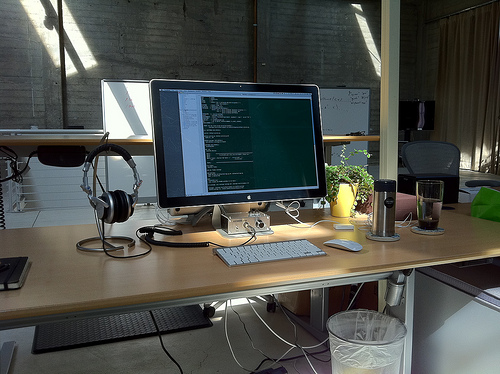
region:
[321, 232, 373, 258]
white wireless computer mouse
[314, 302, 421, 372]
waste basket under the desk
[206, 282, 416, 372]
cords hanging under the desk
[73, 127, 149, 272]
headset on a stand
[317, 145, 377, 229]
plant in a yellow pot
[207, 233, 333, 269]
silver and white computer keyboard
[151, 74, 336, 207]
computer monitor is on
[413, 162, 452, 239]
glass of water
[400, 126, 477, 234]
black desk chair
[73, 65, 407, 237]
whiteboard behind the computer desk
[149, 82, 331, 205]
an apple computer moniter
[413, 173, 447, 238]
a glass of water half full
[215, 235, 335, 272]
a keyboard with white keys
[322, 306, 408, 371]
an empty trash can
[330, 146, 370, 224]
a plant in a yellow pot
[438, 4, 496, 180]
part of a long curtain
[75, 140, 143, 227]
a pair of silver and black headphones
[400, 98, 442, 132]
part of a flat screen tv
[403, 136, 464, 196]
the back of a chair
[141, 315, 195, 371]
a black cable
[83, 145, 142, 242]
headphones hanging on desk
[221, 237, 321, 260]
keyboard on the desk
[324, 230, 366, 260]
mouse on the desk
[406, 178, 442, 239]
glass of the water on desk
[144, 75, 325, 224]
large computer on desk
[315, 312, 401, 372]
garbage can under computer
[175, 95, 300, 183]
screen on desk top computer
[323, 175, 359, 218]
yellow flower pot on desk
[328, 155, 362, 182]
green plant in pot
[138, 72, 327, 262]
computer on desk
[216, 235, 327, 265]
White wireless computer keyboard.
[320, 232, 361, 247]
White wireless computer mouse.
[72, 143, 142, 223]
Silver and black headphones.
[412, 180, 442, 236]
Glass of water sitting on a coaster.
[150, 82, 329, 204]
Flat screen computer moniter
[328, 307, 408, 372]
Waste paper basket with plastic lining.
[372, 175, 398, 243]
Therma coffee container sitting on a coaster.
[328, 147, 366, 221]
Small plant in yellow vase.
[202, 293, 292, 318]
Rollers on an office chair.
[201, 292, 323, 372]
Connection wires to computer.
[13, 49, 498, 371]
an office space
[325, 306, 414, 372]
a wastebasket with a plastic bag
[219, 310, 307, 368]
a bunch of wires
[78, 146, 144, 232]
silvery and black headphones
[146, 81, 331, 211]
a black monitor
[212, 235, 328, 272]
a white keyboard on a wooden desk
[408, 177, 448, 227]
a glass of water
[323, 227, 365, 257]
a white wireless mouse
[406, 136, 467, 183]
the black seat of a chair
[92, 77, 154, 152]
a whiteboard